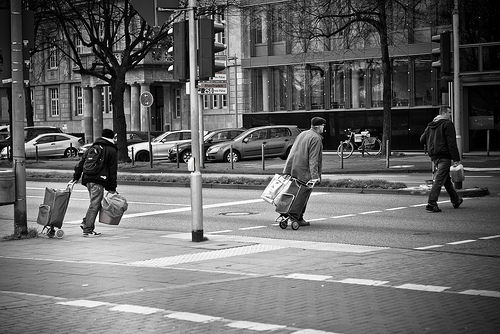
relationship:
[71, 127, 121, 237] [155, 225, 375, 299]
man crossing street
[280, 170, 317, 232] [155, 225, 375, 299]
man dragging bag across street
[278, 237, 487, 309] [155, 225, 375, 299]
white dashes in street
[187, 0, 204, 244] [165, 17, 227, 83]
pole a traffic lights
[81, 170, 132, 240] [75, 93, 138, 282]
bag in hand of a man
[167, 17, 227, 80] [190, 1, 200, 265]
traffic lights on pole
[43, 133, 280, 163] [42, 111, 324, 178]
cars parked in the lot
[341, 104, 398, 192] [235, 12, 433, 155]
bike against building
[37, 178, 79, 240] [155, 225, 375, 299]
briefcase across street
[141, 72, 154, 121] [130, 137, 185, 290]
"the sign on side of the road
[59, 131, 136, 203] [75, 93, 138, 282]
jacket is black in color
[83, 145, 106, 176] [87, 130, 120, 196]
backpack on h back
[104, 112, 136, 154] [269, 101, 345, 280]
cape is black in color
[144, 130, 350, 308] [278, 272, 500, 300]
road has white dashes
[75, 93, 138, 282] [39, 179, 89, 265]
man rolling a briefcase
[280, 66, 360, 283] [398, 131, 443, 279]
man in the middle of crossway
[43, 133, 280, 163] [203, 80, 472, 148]
cars parked on roadside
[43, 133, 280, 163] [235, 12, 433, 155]
cars next to building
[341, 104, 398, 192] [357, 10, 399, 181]
bike near tree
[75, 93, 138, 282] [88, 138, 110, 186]
person wearing a backpack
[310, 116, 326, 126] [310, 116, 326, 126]
cap is a cap is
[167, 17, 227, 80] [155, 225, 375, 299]
traffic lights above street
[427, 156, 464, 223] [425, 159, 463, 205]
man is wearing man is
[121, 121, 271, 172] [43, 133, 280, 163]
front wheel of cars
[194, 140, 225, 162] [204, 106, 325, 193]
headlight on car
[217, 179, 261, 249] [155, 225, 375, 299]
manhole cover on street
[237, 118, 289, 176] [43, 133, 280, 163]
driver's door of cars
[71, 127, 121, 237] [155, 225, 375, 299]
man across street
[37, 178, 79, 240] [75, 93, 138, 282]
briefcase with wheels behind a person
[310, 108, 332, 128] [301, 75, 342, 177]
cap is on a mans head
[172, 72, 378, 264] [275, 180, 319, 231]
large paper man dragging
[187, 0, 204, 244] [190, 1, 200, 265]
pole sign pole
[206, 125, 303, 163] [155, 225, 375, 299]
car on side of street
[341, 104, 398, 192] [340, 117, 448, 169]
bike parked at a curb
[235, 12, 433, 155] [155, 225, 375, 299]
large building on a downtown street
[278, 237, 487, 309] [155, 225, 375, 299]
white dashes on street